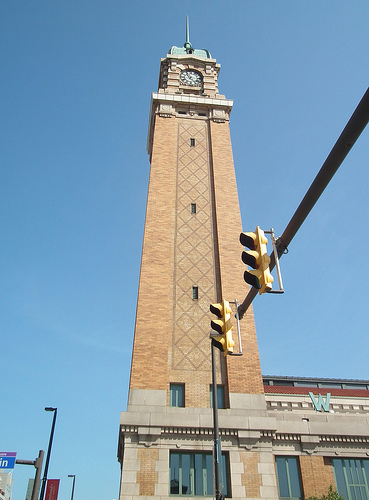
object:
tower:
[126, 12, 264, 417]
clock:
[179, 67, 207, 93]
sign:
[0, 452, 24, 467]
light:
[242, 267, 259, 292]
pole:
[235, 90, 368, 324]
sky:
[0, 0, 368, 499]